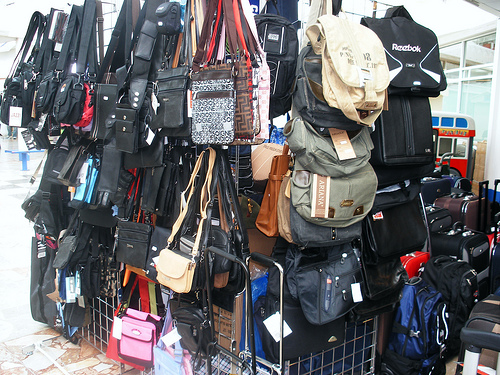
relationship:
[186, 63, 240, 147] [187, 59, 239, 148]
design on purse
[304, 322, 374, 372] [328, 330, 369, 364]
displat on bags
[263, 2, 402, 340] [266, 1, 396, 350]
messenger bags on row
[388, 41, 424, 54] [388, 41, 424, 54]
brand name on brand name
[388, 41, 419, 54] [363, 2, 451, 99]
brand name on bag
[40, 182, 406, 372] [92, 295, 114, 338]
rack has wire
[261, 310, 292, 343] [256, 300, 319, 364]
tag on bag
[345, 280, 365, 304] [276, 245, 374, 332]
tag on bag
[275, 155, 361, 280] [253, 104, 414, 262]
print on bag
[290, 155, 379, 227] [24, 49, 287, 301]
bag on rack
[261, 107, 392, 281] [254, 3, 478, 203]
bag on rack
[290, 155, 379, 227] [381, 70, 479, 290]
bag on rack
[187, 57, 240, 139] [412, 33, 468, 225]
bag on rack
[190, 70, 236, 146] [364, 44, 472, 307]
bag on rack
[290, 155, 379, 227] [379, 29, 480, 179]
bag on rack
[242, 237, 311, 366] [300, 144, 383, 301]
stripe on bag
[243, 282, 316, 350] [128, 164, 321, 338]
tag on bag